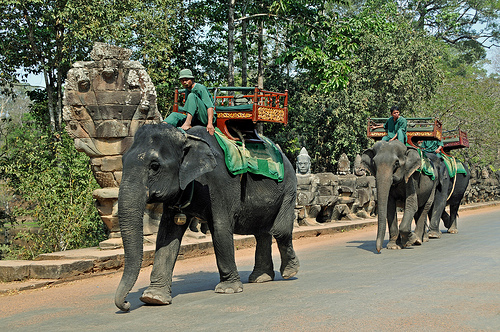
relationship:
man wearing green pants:
[158, 69, 214, 137] [170, 93, 209, 130]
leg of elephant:
[136, 205, 190, 307] [111, 119, 301, 309]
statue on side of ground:
[61, 41, 164, 250] [0, 206, 499, 331]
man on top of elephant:
[158, 69, 214, 137] [111, 119, 301, 309]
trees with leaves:
[19, 3, 496, 158] [270, 20, 310, 52]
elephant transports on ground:
[114, 122, 301, 313] [0, 206, 499, 331]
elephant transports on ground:
[360, 138, 434, 253] [0, 206, 499, 331]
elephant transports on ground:
[435, 149, 470, 235] [0, 206, 499, 331]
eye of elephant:
[146, 156, 158, 165] [114, 122, 301, 313]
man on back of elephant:
[158, 69, 214, 137] [114, 122, 301, 313]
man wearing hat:
[158, 69, 214, 137] [174, 57, 226, 87]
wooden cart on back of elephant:
[363, 112, 444, 142] [360, 138, 434, 253]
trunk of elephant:
[105, 153, 149, 324] [111, 119, 301, 309]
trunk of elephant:
[361, 156, 396, 256] [360, 138, 434, 253]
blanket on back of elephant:
[213, 124, 286, 183] [111, 119, 301, 309]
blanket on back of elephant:
[406, 141, 437, 182] [353, 138, 448, 245]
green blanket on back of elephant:
[439, 148, 464, 176] [444, 153, 468, 235]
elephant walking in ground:
[111, 119, 301, 309] [0, 206, 499, 331]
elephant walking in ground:
[361, 138, 448, 248] [0, 206, 499, 331]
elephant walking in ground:
[435, 149, 470, 235] [0, 206, 499, 331]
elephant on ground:
[111, 119, 301, 309] [0, 206, 499, 331]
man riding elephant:
[158, 69, 214, 137] [107, 112, 310, 300]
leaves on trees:
[2, 5, 493, 157] [3, 3, 494, 246]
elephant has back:
[111, 119, 301, 309] [193, 118, 283, 155]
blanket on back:
[206, 122, 288, 182] [193, 118, 283, 155]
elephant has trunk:
[114, 122, 301, 313] [98, 167, 157, 311]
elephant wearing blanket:
[111, 119, 301, 309] [211, 126, 286, 182]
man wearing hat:
[158, 69, 214, 137] [176, 68, 195, 79]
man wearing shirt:
[382, 106, 409, 145] [384, 114, 409, 138]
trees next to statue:
[3, 118, 114, 259] [50, 35, 162, 252]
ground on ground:
[0, 206, 499, 331] [0, 206, 499, 331]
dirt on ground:
[0, 200, 498, 320] [0, 206, 499, 331]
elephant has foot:
[111, 119, 301, 309] [139, 284, 175, 307]